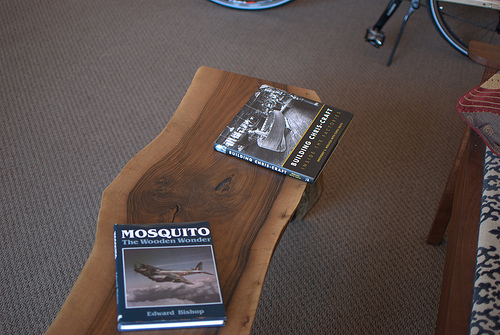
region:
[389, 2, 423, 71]
a kick stand of a bike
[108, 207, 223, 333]
a book on a coffee table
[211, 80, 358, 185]
a book on a coffee table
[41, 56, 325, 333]
a coffee table made of wood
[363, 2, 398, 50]
the peddle of a bike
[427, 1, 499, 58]
a tire of a bike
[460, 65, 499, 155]
a decor pillow on couch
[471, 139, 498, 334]
a black and blue cushion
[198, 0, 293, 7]
the tire of a bike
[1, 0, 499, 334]
grey carpet in a room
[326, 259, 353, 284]
patch of brown carpet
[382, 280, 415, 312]
patch of brown carpet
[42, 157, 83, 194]
patch of brown carpet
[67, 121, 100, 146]
patch of brown carpet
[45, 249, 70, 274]
patch of brown carpet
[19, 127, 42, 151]
patch of brown carpet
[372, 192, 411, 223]
patch of brown carpet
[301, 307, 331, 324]
patch of brown carpet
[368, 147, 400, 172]
patch of brown carpet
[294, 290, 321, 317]
patch of brown carpet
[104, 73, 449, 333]
a wooden table with books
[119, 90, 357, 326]
a wooden table with two books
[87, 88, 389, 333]
a brown table with books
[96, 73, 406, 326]
a brown table with two books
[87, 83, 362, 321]
a coffee table with two books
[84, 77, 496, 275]
a coffee table with books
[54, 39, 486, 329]
books on at able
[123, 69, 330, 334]
two books on a table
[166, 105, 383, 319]
books on a brown table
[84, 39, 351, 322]
books on a wooden table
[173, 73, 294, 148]
books on a table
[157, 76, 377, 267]
books on a wood table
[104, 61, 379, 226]
books on a brown wood table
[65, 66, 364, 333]
two books on a brown table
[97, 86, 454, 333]
two boooks on a wooden table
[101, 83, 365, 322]
two books on a brown wood tables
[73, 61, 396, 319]
a brown coffe table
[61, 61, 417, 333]
a wood coffe table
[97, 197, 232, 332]
THE BOOK IS BLUE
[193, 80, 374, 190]
THE BOOK IS BLACK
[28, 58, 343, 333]
THE TABLE IS WOODEN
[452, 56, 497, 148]
THE PILLOW IS ON THE COUCH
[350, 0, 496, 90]
THE BIKE IS INSIDE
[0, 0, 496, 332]
THE CARPET IS BEIGE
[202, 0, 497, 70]
THE BIKE IS PARKED ON THE CARPET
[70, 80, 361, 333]
TWO BOOKS ON THE TABLE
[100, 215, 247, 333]
THE BOOK IS BY EDWARD BISHOP